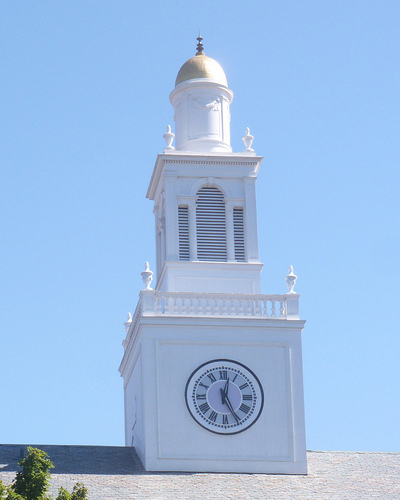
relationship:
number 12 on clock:
[217, 366, 228, 383] [178, 356, 272, 440]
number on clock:
[230, 370, 240, 384] [181, 354, 268, 443]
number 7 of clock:
[206, 410, 221, 423] [182, 356, 264, 434]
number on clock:
[194, 389, 208, 404] [186, 360, 265, 436]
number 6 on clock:
[221, 415, 231, 428] [182, 356, 264, 434]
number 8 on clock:
[196, 400, 212, 415] [174, 361, 275, 433]